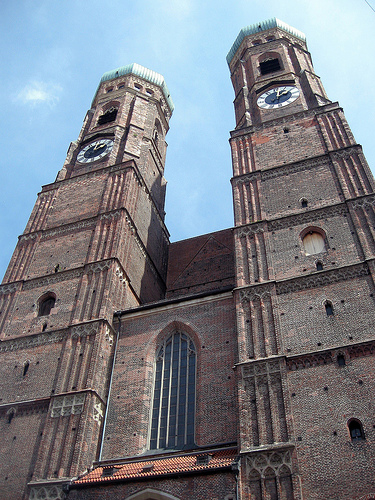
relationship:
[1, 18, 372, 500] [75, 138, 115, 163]
building has clock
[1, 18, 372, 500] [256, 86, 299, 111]
building has clock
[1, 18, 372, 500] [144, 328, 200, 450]
building has window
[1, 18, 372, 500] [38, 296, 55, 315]
building has window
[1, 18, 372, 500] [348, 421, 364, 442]
building has window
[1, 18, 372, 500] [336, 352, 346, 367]
building has window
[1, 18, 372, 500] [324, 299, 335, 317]
building has window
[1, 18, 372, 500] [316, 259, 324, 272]
building has window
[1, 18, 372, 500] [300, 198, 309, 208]
building has window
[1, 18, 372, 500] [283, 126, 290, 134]
building has window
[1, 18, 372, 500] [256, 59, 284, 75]
building has window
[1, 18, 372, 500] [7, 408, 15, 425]
building has window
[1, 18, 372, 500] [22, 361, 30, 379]
building has window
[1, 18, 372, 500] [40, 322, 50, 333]
building has window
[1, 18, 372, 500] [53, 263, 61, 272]
building has window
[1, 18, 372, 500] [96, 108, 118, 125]
building has window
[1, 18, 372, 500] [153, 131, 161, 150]
building has window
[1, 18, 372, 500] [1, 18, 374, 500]
building has building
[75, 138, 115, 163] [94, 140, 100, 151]
clock has hand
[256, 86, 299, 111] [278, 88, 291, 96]
clock has hand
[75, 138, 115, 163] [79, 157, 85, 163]
clock has roman numeral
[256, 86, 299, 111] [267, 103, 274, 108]
clock has roman numeral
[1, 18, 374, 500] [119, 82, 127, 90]
building has window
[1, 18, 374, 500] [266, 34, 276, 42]
building has window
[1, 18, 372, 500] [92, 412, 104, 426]
building has hole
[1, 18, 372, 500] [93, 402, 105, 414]
building has hole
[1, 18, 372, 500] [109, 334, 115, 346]
building has hole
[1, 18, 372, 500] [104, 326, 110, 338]
building has hole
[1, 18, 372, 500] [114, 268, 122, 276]
building has hole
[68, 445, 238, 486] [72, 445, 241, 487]
roof made of tile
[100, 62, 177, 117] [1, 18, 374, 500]
parapet on top of building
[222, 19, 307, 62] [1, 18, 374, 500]
parapet on top of building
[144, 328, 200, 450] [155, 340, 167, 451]
window has mullion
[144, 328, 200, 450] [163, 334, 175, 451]
window has mullion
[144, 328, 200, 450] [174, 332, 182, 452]
window has mullion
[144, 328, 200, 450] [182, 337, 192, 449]
window has mullion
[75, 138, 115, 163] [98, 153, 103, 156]
clock has roman numeral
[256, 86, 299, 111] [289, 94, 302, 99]
clock has roman numeral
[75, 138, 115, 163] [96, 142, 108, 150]
clock has hand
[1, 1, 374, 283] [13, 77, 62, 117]
sky has cloud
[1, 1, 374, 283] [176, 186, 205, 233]
sky has cloud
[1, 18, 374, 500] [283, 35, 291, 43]
building has window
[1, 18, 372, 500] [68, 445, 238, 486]
building has roof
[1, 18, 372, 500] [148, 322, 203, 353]
building has arch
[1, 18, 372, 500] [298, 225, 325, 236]
building has arch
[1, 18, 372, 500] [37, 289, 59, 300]
building has arch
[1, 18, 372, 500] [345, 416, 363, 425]
building has arch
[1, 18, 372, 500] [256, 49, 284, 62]
building has arch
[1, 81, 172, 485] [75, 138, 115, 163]
wall has clock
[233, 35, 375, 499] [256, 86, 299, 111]
wall has clock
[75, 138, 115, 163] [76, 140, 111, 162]
clock has dial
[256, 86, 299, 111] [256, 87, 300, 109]
clock has dial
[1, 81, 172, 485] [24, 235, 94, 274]
wall made of bricks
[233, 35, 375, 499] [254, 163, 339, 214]
wall made of bricks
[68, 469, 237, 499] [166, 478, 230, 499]
wall made of bricks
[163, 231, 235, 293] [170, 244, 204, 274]
wall made of bricks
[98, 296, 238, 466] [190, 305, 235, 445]
wall made of bricks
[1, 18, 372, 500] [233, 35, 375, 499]
building has wall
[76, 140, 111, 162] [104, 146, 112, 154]
dial has roman numeral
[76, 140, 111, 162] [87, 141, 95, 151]
dial has roman numeral